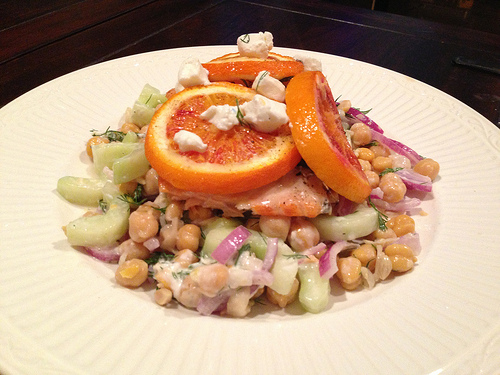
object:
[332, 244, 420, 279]
peas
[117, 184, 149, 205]
herb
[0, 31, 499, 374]
food/white plate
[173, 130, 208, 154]
cheese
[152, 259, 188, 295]
creamy substance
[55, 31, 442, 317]
food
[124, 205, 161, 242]
bean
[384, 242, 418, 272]
garbanzo beans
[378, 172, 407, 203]
garbanzo beans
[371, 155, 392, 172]
garbanzo beans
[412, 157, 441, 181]
garbanzo beans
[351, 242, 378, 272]
garbanzo beans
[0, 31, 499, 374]
plate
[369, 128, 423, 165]
onion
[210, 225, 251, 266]
onion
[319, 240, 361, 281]
onion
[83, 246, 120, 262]
onion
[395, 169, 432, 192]
onion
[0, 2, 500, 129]
table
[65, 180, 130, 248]
celery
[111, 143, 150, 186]
celery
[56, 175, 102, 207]
celery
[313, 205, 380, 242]
celery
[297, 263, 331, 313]
celery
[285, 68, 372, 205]
blood orange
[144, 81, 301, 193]
blood orange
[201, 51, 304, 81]
blood orange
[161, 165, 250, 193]
orange rind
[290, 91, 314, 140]
orange rind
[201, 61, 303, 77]
orange rind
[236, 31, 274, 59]
cheese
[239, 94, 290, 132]
white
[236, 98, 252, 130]
herb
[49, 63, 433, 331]
food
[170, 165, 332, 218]
sauce